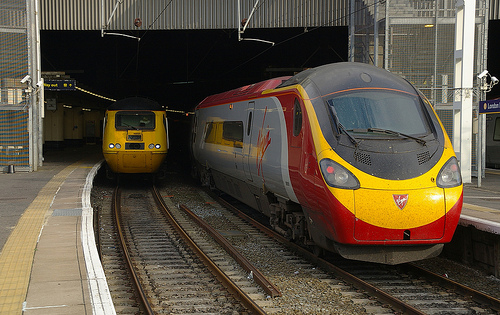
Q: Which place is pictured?
A: It is a train station.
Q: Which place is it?
A: It is a train station.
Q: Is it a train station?
A: Yes, it is a train station.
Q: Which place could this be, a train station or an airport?
A: It is a train station.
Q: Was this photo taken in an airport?
A: No, the picture was taken in a train station.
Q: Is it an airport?
A: No, it is a train station.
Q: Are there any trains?
A: Yes, there is a train.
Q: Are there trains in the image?
A: Yes, there is a train.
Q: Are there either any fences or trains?
A: Yes, there is a train.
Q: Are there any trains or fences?
A: Yes, there is a train.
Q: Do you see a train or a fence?
A: Yes, there is a train.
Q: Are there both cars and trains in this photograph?
A: No, there is a train but no cars.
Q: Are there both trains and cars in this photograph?
A: No, there is a train but no cars.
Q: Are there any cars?
A: No, there are no cars.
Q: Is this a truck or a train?
A: This is a train.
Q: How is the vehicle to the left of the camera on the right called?
A: The vehicle is a train.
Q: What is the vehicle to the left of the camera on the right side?
A: The vehicle is a train.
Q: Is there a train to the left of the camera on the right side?
A: Yes, there is a train to the left of the camera.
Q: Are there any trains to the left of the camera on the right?
A: Yes, there is a train to the left of the camera.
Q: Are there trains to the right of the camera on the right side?
A: No, the train is to the left of the camera.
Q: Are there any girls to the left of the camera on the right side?
A: No, there is a train to the left of the camera.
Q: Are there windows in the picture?
A: Yes, there is a window.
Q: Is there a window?
A: Yes, there is a window.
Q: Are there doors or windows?
A: Yes, there is a window.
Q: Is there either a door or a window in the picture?
A: Yes, there is a window.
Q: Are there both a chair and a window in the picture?
A: No, there is a window but no chairs.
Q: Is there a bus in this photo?
A: No, there are no buses.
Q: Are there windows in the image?
A: Yes, there is a window.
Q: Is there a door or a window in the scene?
A: Yes, there is a window.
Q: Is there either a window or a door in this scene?
A: Yes, there is a window.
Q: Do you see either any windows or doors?
A: Yes, there is a window.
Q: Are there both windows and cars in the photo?
A: No, there is a window but no cars.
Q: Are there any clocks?
A: No, there are no clocks.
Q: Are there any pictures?
A: No, there are no pictures.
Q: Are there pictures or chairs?
A: No, there are no pictures or chairs.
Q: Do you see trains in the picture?
A: Yes, there is a train.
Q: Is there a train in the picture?
A: Yes, there is a train.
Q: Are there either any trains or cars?
A: Yes, there is a train.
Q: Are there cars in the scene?
A: No, there are no cars.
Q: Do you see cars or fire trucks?
A: No, there are no cars or fire trucks.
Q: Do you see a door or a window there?
A: Yes, there is a window.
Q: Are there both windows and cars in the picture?
A: No, there is a window but no cars.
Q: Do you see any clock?
A: No, there are no clocks.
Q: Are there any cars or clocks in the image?
A: No, there are no clocks or cars.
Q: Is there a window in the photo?
A: Yes, there is a window.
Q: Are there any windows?
A: Yes, there is a window.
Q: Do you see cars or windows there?
A: Yes, there is a window.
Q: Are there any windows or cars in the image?
A: Yes, there is a window.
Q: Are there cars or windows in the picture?
A: Yes, there is a window.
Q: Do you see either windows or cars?
A: Yes, there is a window.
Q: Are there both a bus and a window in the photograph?
A: No, there is a window but no buses.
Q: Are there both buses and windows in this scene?
A: No, there is a window but no buses.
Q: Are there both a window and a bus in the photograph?
A: No, there is a window but no buses.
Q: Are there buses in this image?
A: No, there are no buses.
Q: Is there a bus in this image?
A: No, there are no buses.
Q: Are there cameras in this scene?
A: Yes, there is a camera.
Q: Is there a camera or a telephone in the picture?
A: Yes, there is a camera.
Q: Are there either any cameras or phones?
A: Yes, there is a camera.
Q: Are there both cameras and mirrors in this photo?
A: No, there is a camera but no mirrors.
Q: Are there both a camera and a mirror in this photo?
A: No, there is a camera but no mirrors.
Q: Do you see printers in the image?
A: No, there are no printers.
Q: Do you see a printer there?
A: No, there are no printers.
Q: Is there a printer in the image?
A: No, there are no printers.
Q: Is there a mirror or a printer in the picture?
A: No, there are no printers or mirrors.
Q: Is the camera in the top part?
A: Yes, the camera is in the top of the image.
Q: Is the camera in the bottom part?
A: No, the camera is in the top of the image.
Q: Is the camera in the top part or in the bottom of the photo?
A: The camera is in the top of the image.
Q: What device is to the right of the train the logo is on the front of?
A: The device is a camera.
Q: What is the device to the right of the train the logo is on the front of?
A: The device is a camera.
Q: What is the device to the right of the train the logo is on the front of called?
A: The device is a camera.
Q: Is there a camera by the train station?
A: Yes, there is a camera by the train station.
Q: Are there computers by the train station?
A: No, there is a camera by the train station.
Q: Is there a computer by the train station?
A: No, there is a camera by the train station.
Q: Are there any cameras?
A: Yes, there is a camera.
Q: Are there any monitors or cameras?
A: Yes, there is a camera.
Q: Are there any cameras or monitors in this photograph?
A: Yes, there is a camera.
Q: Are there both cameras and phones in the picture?
A: No, there is a camera but no phones.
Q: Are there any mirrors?
A: No, there are no mirrors.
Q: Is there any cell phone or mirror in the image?
A: No, there are no mirrors or cell phones.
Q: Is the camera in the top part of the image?
A: Yes, the camera is in the top of the image.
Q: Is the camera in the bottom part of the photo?
A: No, the camera is in the top of the image.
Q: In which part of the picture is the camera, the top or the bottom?
A: The camera is in the top of the image.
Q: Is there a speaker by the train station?
A: No, there is a camera by the train station.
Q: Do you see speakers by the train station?
A: No, there is a camera by the train station.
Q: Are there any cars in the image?
A: No, there are no cars.